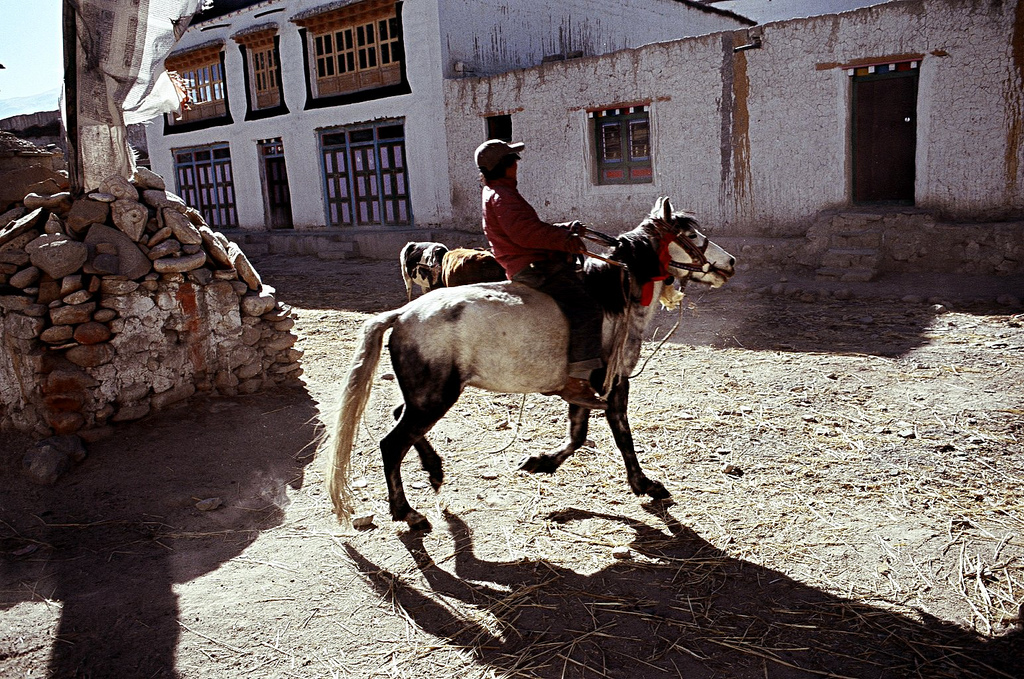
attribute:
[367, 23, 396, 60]
window pane — glass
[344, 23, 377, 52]
window pane — glass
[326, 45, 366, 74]
window pane — glass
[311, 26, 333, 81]
window pane — glass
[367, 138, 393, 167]
window pane — glass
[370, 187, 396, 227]
window pane — glass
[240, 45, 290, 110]
window pane — glass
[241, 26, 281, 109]
window pane — glass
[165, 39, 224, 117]
window pane — glass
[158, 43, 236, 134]
window pane — glass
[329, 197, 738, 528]
horse — white, black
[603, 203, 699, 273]
mane — black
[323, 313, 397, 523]
tail — white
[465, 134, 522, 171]
hat — grey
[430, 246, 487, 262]
cow — black and white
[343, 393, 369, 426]
tail — long and white